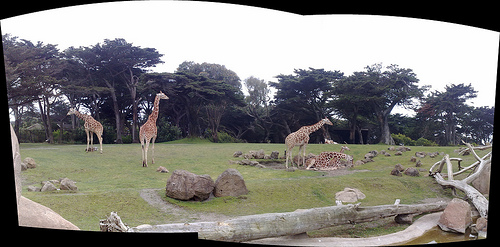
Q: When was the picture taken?
A: Daytime.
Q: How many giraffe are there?
A: Three.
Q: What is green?
A: Grass.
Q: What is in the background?
A: Trees.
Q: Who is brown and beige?
A: Giraffe.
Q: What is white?
A: Sky.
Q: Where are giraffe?
A: On a grassy field.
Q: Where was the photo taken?
A: At a zoo.